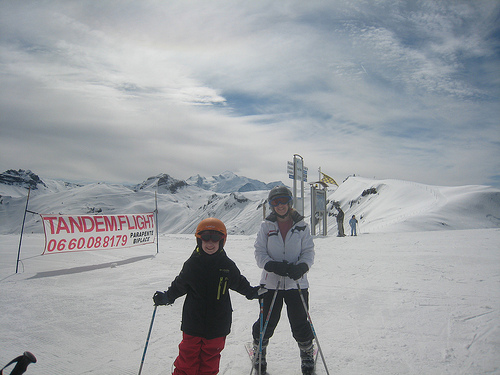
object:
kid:
[152, 218, 270, 375]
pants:
[170, 330, 226, 374]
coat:
[162, 245, 258, 339]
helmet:
[193, 216, 228, 255]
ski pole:
[136, 301, 158, 374]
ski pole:
[257, 296, 264, 374]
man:
[251, 185, 315, 374]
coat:
[252, 208, 316, 292]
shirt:
[275, 212, 295, 242]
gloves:
[286, 261, 310, 281]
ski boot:
[251, 338, 271, 374]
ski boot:
[294, 339, 317, 375]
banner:
[39, 208, 158, 256]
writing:
[44, 215, 157, 254]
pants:
[251, 286, 316, 342]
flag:
[320, 171, 337, 188]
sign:
[313, 189, 325, 213]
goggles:
[267, 195, 294, 207]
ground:
[3, 228, 498, 374]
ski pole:
[295, 278, 330, 374]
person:
[334, 207, 345, 236]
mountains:
[1, 167, 499, 235]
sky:
[1, 0, 500, 190]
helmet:
[267, 186, 294, 218]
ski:
[243, 342, 255, 362]